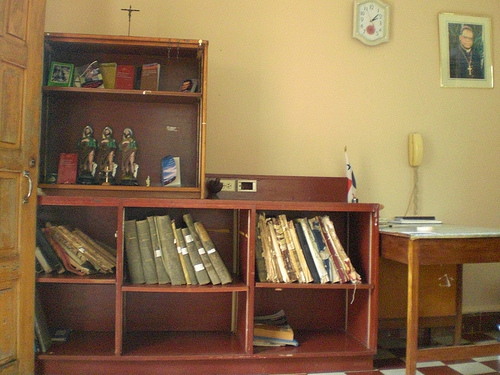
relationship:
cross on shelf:
[121, 3, 141, 38] [39, 32, 209, 199]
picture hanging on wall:
[438, 11, 493, 83] [44, 1, 499, 318]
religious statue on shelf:
[77, 123, 100, 186] [39, 32, 209, 199]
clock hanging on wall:
[351, 1, 391, 47] [44, 1, 499, 318]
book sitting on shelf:
[148, 215, 172, 283] [35, 175, 384, 374]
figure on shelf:
[118, 126, 140, 187] [39, 32, 209, 199]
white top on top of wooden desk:
[412, 225, 439, 235] [378, 225, 498, 375]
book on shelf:
[141, 64, 161, 90] [39, 32, 209, 199]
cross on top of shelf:
[121, 3, 141, 38] [39, 32, 209, 199]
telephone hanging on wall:
[406, 131, 424, 167] [44, 1, 499, 318]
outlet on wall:
[218, 177, 237, 189] [44, 1, 499, 318]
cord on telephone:
[412, 167, 419, 218] [406, 131, 424, 167]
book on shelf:
[139, 219, 157, 284] [35, 175, 384, 374]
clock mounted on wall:
[351, 1, 391, 47] [44, 1, 499, 318]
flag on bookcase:
[344, 143, 358, 201] [35, 175, 384, 374]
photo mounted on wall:
[446, 21, 485, 79] [44, 1, 499, 318]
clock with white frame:
[351, 1, 391, 47] [352, 0, 392, 48]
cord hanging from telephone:
[412, 167, 419, 218] [406, 131, 424, 167]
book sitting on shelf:
[258, 221, 270, 282] [35, 175, 384, 374]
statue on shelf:
[97, 126, 119, 185] [39, 32, 209, 199]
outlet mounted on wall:
[236, 180, 257, 191] [44, 1, 499, 318]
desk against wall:
[377, 218, 499, 373] [44, 1, 499, 318]